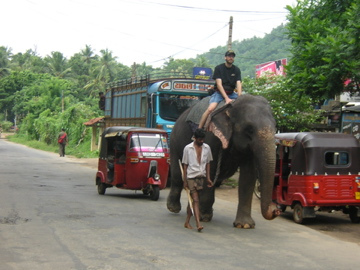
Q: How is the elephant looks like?
A: Good.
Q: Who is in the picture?
A: Two men.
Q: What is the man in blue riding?
A: An elephant.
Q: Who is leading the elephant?
A: An Indian.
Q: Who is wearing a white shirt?
A: The Indian.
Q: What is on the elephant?
A: A man is on the elephant.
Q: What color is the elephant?
A: The elephant is grey.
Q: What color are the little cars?
A: The little cars are red.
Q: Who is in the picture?
A: People driving the cars,a man walking the elephant and a man riding the elephant are in the picture.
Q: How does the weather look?
A: The weather looks sunny.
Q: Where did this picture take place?
A: It took place in a small town.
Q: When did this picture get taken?
A: It was taken in the day time.